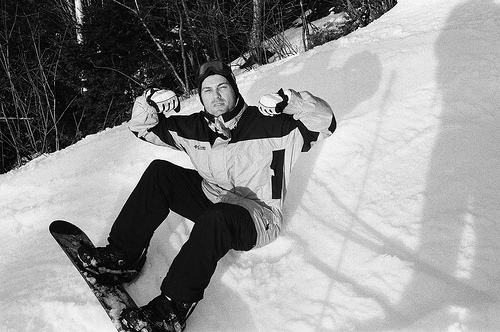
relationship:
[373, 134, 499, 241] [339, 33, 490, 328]
snow on slope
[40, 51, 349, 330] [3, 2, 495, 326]
snowboarder in snow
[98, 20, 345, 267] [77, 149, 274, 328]
man wearing pants